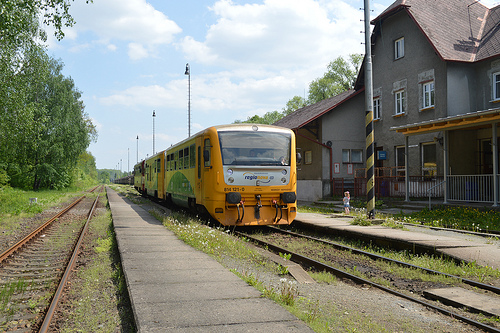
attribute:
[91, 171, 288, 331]
concrete — grey.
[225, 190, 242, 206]
bumper — black, metal 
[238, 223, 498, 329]
track — Rusted, metal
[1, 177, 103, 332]
track — Rusted, metal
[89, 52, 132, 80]
sky — blue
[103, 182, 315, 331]
sidewalk — wooden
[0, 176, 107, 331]
tracks — straight.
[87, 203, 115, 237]
grass — small, green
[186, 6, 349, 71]
clouds — white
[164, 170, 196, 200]
illustration — black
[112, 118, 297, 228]
train — yellow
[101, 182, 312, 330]
walkway — gray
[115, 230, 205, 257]
section — medium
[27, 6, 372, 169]
sky — cloudy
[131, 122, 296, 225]
train — yellow, yellow.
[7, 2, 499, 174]
cloud — small, white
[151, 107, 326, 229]
train — yellow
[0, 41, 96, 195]
tree — tall, thick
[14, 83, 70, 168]
green leaves — light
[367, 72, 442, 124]
windows — Three, side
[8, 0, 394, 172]
sky — blue, small, patch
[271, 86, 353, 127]
roof — brown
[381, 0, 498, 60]
roof — brown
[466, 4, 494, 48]
part — small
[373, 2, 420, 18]
part — small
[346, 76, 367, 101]
part — small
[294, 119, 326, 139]
part — small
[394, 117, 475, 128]
part — small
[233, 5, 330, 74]
clouds — white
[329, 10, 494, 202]
house — tall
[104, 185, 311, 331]
panels — Gray asphalt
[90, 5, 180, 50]
clouds — white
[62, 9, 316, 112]
sky — blue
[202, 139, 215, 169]
window — side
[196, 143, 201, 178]
window — side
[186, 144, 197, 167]
window — side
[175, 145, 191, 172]
window — side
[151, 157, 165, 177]
window — side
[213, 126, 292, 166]
window — Large, clear, glass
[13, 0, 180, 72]
cloud — white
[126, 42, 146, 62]
cloud — white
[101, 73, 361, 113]
cloud — white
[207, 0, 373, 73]
cloud — white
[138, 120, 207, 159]
cloud — white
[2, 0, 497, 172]
sky — blue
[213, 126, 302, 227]
front — Yellow, painted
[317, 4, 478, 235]
building — gray 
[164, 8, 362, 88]
clouds — white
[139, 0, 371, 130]
clouds — white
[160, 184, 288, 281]
grass — gray